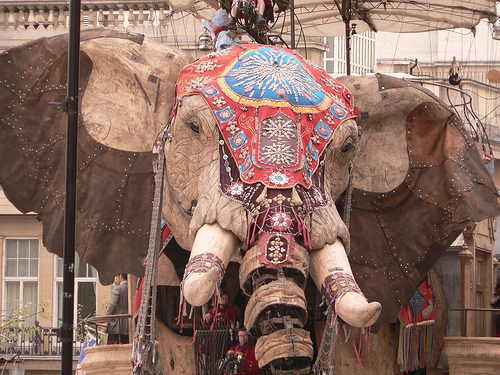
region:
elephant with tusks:
[11, 6, 482, 369]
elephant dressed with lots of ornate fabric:
[21, 36, 456, 363]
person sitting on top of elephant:
[182, 12, 253, 52]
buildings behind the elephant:
[0, 0, 490, 331]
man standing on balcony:
[1, 205, 127, 345]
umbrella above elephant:
[275, 0, 476, 97]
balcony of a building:
[1, 2, 326, 59]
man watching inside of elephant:
[216, 321, 256, 372]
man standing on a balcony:
[200, 285, 241, 342]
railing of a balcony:
[184, 321, 238, 372]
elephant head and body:
[2, 28, 496, 370]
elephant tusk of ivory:
[186, 223, 227, 306]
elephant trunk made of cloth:
[243, 236, 318, 366]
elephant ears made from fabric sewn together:
[361, 73, 486, 225]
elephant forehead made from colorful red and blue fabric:
[183, 61, 358, 186]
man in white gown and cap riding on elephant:
[211, 11, 243, 48]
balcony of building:
[75, 317, 141, 366]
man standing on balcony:
[106, 274, 132, 340]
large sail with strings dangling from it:
[271, 0, 483, 33]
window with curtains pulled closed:
[2, 237, 40, 323]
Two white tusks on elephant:
[152, 205, 385, 348]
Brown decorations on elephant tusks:
[170, 245, 377, 312]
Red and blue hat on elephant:
[189, 29, 356, 206]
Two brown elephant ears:
[2, 15, 498, 340]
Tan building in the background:
[1, 2, 498, 367]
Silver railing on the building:
[432, 290, 498, 355]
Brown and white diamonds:
[264, 229, 292, 269]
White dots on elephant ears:
[0, 42, 162, 273]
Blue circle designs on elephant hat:
[221, 45, 326, 108]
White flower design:
[270, 212, 291, 229]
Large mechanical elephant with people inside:
[3, 32, 487, 371]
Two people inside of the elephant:
[207, 295, 256, 369]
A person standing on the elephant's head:
[197, 1, 242, 51]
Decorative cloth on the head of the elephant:
[180, 39, 358, 191]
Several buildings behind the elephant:
[9, 5, 499, 364]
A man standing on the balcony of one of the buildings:
[103, 268, 138, 343]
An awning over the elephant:
[177, 0, 497, 44]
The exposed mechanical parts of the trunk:
[242, 237, 323, 369]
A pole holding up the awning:
[54, 2, 84, 365]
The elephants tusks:
[174, 216, 384, 323]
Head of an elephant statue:
[155, 43, 358, 255]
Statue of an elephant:
[0, 27, 498, 372]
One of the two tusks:
[307, 237, 381, 328]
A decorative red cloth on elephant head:
[173, 43, 359, 187]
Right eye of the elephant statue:
[188, 121, 199, 133]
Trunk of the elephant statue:
[241, 239, 312, 374]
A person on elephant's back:
[210, 8, 240, 50]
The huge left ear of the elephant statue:
[335, 74, 499, 331]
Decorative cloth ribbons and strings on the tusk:
[320, 273, 371, 368]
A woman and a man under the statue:
[204, 291, 256, 373]